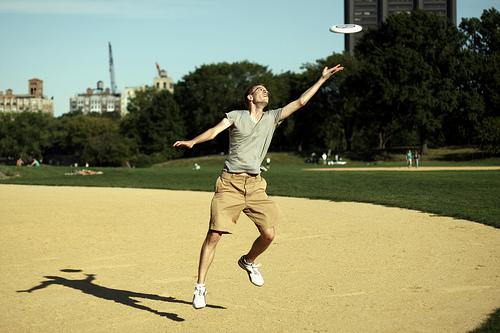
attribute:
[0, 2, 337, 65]
sky — blue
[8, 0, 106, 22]
cloud — white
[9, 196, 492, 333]
sand — brown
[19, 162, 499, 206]
grass — green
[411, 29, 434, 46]
leaves — green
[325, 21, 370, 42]
frisbee — white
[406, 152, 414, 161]
shirt — green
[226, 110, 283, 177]
shirt — tan, dull green, gray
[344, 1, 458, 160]
building — tall, brown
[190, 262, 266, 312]
shoes — white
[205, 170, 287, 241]
shorts — brown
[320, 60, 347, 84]
hand — raised